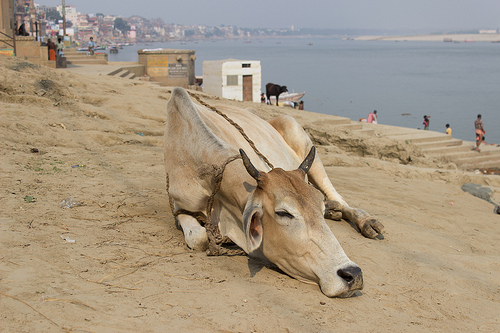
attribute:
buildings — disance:
[35, 2, 326, 47]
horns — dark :
[216, 131, 329, 192]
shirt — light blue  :
[87, 42, 93, 49]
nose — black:
[332, 260, 363, 287]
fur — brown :
[200, 87, 278, 172]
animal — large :
[164, 84, 386, 297]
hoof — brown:
[353, 215, 386, 242]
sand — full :
[12, 57, 488, 328]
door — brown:
[240, 74, 255, 100]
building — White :
[186, 62, 275, 97]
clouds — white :
[310, 7, 344, 22]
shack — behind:
[202, 58, 266, 99]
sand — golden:
[356, 144, 476, 307]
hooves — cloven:
[327, 199, 385, 246]